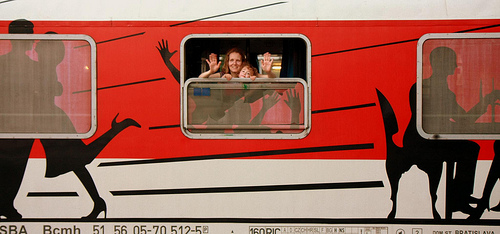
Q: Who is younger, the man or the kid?
A: The kid is younger than the man.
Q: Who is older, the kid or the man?
A: The man is older than the kid.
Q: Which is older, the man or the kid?
A: The man is older than the kid.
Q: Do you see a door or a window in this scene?
A: Yes, there are windows.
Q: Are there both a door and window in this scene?
A: No, there are windows but no doors.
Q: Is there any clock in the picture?
A: No, there are no clocks.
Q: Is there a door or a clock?
A: No, there are no clocks or doors.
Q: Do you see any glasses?
A: No, there are no glasses.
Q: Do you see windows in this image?
A: Yes, there is a window.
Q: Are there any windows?
A: Yes, there is a window.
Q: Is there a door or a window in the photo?
A: Yes, there is a window.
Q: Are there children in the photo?
A: Yes, there is a child.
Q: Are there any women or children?
A: Yes, there is a child.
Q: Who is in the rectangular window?
A: The child is in the window.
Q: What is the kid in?
A: The kid is in the window.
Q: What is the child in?
A: The kid is in the window.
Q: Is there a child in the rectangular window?
A: Yes, there is a child in the window.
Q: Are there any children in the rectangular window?
A: Yes, there is a child in the window.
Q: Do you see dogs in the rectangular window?
A: No, there is a child in the window.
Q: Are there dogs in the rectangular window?
A: No, there is a child in the window.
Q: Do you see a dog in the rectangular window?
A: No, there is a child in the window.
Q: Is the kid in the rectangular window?
A: Yes, the kid is in the window.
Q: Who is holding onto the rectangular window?
A: The child is holding onto the window.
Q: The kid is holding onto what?
A: The kid is holding onto the window.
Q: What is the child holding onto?
A: The kid is holding onto the window.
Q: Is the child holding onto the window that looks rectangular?
A: Yes, the child is holding onto the window.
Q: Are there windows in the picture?
A: Yes, there is a window.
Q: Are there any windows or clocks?
A: Yes, there is a window.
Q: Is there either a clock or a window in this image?
A: Yes, there is a window.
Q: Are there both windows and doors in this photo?
A: No, there is a window but no doors.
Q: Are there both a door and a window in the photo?
A: No, there is a window but no doors.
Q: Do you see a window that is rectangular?
A: Yes, there is a rectangular window.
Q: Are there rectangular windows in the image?
A: Yes, there is a rectangular window.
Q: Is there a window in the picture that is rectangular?
A: Yes, there is a window that is rectangular.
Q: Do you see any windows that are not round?
A: Yes, there is a rectangular window.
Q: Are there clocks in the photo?
A: No, there are no clocks.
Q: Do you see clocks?
A: No, there are no clocks.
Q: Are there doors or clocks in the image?
A: No, there are no clocks or doors.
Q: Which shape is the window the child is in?
A: The window is rectangular.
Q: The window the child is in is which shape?
A: The window is rectangular.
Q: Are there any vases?
A: No, there are no vases.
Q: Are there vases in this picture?
A: No, there are no vases.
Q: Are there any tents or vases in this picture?
A: No, there are no vases or tents.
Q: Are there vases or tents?
A: No, there are no vases or tents.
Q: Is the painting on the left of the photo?
A: Yes, the painting is on the left of the image.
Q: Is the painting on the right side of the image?
A: No, the painting is on the left of the image.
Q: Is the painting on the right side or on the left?
A: The painting is on the left of the image.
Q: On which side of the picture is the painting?
A: The painting is on the left of the image.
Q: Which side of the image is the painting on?
A: The painting is on the left of the image.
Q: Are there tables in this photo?
A: Yes, there is a table.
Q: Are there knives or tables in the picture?
A: Yes, there is a table.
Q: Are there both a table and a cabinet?
A: No, there is a table but no cabinets.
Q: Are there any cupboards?
A: No, there are no cupboards.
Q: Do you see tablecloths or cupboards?
A: No, there are no cupboards or tablecloths.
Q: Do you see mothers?
A: No, there are no mothers.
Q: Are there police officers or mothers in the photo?
A: No, there are no mothers or police officers.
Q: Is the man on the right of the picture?
A: Yes, the man is on the right of the image.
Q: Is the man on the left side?
A: No, the man is on the right of the image.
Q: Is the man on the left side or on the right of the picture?
A: The man is on the right of the image.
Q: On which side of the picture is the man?
A: The man is on the right of the image.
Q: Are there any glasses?
A: No, there are no glasses.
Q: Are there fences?
A: No, there are no fences.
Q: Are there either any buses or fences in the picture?
A: No, there are no fences or buses.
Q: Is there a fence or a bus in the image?
A: No, there are no fences or buses.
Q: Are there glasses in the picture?
A: No, there are no glasses.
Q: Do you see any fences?
A: No, there are no fences.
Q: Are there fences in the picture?
A: No, there are no fences.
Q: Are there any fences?
A: No, there are no fences.